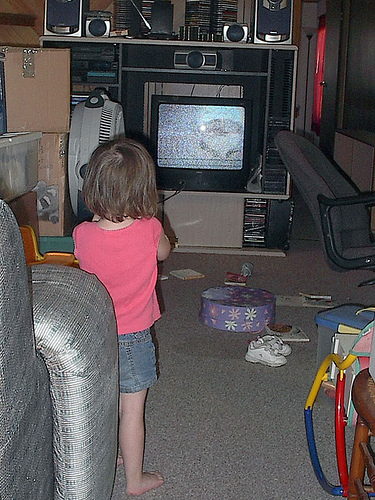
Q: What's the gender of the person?
A: Female.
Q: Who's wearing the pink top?
A: Girl.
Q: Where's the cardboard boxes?
A: Left of TV.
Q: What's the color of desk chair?
A: Grey.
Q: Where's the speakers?
A: Above TV.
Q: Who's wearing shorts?
A: Girl.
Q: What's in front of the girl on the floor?
A: Toys.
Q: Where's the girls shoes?
A: Floor.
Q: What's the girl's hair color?
A: Brown.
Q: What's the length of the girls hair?
A: Short.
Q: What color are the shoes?
A: White.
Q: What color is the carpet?
A: Gray.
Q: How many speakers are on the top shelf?
A: Four.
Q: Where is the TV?
A: Entertainment center.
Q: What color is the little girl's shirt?
A: Pink.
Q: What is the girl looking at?
A: TV.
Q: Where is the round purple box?
A: Floor.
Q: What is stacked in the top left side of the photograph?
A: Boxes.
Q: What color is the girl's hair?
A: Brown.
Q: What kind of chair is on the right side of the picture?
A: Office chair.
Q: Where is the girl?
A: In a living room.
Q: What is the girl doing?
A: Watching TV.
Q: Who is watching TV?
A: A girl in pink.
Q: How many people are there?
A: One.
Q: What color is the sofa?
A: Silver.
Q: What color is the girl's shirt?
A: Pink.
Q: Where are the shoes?
A: In the middle of the floor.